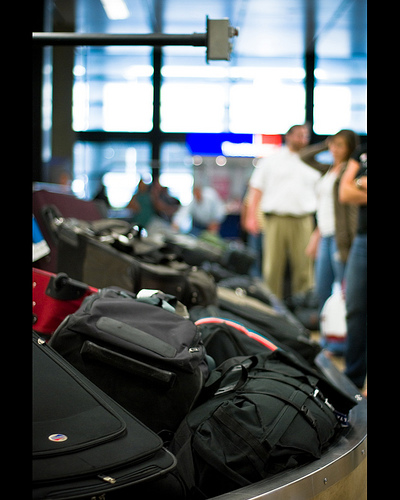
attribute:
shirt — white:
[254, 146, 320, 233]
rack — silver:
[180, 435, 366, 496]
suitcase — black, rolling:
[32, 354, 168, 492]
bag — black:
[212, 361, 325, 468]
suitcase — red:
[35, 265, 99, 353]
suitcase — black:
[83, 295, 203, 408]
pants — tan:
[261, 204, 316, 324]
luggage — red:
[35, 264, 52, 341]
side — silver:
[245, 470, 323, 499]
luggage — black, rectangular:
[41, 380, 124, 469]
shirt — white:
[316, 173, 342, 234]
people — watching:
[250, 113, 381, 357]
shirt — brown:
[338, 203, 359, 258]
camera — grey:
[206, 19, 231, 63]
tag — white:
[140, 283, 187, 319]